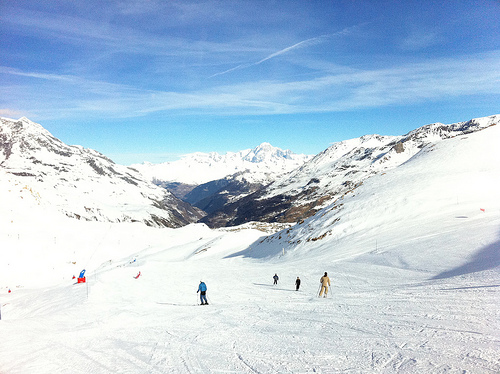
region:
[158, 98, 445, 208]
blue sky above mountain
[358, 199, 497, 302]
snow on hill of mountain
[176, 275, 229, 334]
skiier wearing blue jacket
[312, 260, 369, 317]
skiier wearing yellow outfit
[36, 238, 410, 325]
skiiers skiing on mountain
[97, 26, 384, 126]
white clouds in blue sky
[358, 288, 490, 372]
ski marks in snow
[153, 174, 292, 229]
shade on the mountain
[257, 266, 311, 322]
skiiers wearing dark colors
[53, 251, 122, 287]
red and blue marker in snow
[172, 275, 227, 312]
blue man on snow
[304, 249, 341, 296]
beige woman on snow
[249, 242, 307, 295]
people in distance on snow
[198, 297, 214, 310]
feet of the man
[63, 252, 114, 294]
man on the left in snow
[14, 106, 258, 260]
mountains with snow on left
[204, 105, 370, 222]
mountains in the distance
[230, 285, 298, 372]
ski print in snow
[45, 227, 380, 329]
people walking in the snow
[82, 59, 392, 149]
blue skies at the top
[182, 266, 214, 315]
the blue colored dressed man skating in the mountains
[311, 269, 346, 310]
the man with yellow colored dress skating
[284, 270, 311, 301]
the black colored man skating in the mountains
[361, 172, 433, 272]
the white colored mountains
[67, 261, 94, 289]
the red colored bench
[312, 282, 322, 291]
the stick used for skating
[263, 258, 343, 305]
three men skating in the mountains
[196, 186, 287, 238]
the black colored rocks in the mountains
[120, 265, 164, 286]
the red colored flag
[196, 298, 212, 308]
the black colored skating shoe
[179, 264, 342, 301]
Four people skiing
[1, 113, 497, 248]
The mountains are tall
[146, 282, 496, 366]
The snow is white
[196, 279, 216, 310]
The person wearing blue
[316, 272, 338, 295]
The person wearing beighe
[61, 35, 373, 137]
The sky is blue and clear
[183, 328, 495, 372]
The tracks in the snow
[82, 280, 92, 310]
The post in the snow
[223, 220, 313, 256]
The shadow of the mountain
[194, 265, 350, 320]
The people are skiing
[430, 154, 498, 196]
ground covered in snow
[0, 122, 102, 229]
mountainside covered in snow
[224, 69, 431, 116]
light clouds in sky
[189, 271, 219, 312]
person in blue and black clothing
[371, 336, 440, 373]
ski tracks in snow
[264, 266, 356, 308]
group of people skiing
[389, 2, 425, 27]
clear blue cloudless sky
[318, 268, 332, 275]
man in black ski mask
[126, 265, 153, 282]
orange plastic safety netting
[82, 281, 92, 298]
brown pole sticking out of snow